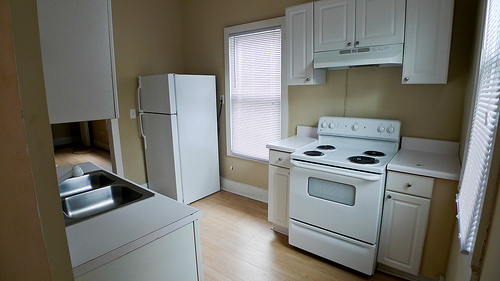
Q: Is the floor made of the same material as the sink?
A: No, the floor is made of wood and the sink is made of metal.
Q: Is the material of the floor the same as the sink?
A: No, the floor is made of wood and the sink is made of metal.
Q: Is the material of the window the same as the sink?
A: No, the window is made of glass and the sink is made of metal.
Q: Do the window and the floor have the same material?
A: No, the window is made of glass and the floor is made of wood.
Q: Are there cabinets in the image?
A: Yes, there is a cabinet.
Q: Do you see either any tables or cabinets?
A: Yes, there is a cabinet.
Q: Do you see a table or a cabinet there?
A: Yes, there is a cabinet.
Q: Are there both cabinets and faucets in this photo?
A: Yes, there are both a cabinet and a faucet.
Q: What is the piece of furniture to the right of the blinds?
A: The piece of furniture is a cabinet.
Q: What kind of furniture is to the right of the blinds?
A: The piece of furniture is a cabinet.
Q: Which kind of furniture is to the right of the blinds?
A: The piece of furniture is a cabinet.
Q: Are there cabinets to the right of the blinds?
A: Yes, there is a cabinet to the right of the blinds.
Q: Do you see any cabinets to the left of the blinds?
A: No, the cabinet is to the right of the blinds.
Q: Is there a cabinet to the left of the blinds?
A: No, the cabinet is to the right of the blinds.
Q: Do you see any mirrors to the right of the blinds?
A: No, there is a cabinet to the right of the blinds.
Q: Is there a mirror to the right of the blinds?
A: No, there is a cabinet to the right of the blinds.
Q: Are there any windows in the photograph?
A: Yes, there is a window.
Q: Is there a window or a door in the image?
A: Yes, there is a window.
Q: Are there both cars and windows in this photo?
A: No, there is a window but no cars.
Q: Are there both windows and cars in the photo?
A: No, there is a window but no cars.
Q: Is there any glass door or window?
A: Yes, there is a glass window.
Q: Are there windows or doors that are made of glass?
A: Yes, the window is made of glass.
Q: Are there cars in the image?
A: No, there are no cars.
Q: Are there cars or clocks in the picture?
A: No, there are no cars or clocks.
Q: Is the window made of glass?
A: Yes, the window is made of glass.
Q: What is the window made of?
A: The window is made of glass.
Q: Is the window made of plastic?
A: No, the window is made of glass.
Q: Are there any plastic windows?
A: No, there is a window but it is made of glass.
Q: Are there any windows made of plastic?
A: No, there is a window but it is made of glass.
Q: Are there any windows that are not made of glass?
A: No, there is a window but it is made of glass.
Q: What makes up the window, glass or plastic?
A: The window is made of glass.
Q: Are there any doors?
A: Yes, there is a door.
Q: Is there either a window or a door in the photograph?
A: Yes, there is a door.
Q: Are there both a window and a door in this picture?
A: Yes, there are both a door and a window.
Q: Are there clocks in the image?
A: No, there are no clocks.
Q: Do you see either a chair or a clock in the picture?
A: No, there are no clocks or chairs.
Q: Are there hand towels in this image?
A: No, there are no hand towels.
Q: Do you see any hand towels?
A: No, there are no hand towels.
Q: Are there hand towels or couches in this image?
A: No, there are no hand towels or couches.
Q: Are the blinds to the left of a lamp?
A: No, the blinds are to the left of the cabinet.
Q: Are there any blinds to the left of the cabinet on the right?
A: Yes, there are blinds to the left of the cabinet.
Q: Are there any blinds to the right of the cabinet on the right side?
A: No, the blinds are to the left of the cabinet.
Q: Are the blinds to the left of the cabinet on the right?
A: Yes, the blinds are to the left of the cabinet.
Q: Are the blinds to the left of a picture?
A: No, the blinds are to the left of the cabinet.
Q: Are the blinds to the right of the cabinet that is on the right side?
A: No, the blinds are to the left of the cabinet.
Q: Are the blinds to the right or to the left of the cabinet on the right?
A: The blinds are to the left of the cabinet.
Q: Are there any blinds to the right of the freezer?
A: Yes, there are blinds to the right of the freezer.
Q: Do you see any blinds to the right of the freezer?
A: Yes, there are blinds to the right of the freezer.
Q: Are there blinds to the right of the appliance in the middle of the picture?
A: Yes, there are blinds to the right of the freezer.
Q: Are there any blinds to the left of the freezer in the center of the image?
A: No, the blinds are to the right of the freezer.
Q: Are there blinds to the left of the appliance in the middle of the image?
A: No, the blinds are to the right of the freezer.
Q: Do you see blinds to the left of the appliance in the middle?
A: No, the blinds are to the right of the freezer.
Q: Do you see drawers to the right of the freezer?
A: No, there are blinds to the right of the freezer.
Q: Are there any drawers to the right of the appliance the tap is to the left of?
A: No, there are blinds to the right of the freezer.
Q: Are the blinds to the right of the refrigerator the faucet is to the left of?
A: Yes, the blinds are to the right of the freezer.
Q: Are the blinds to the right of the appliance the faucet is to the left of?
A: Yes, the blinds are to the right of the freezer.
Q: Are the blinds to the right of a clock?
A: No, the blinds are to the right of the freezer.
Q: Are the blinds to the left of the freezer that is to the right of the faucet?
A: No, the blinds are to the right of the refrigerator.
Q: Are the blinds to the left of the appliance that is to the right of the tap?
A: No, the blinds are to the right of the refrigerator.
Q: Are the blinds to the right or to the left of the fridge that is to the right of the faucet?
A: The blinds are to the right of the fridge.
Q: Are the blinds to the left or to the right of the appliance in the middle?
A: The blinds are to the right of the fridge.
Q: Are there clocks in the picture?
A: No, there are no clocks.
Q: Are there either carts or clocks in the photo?
A: No, there are no clocks or carts.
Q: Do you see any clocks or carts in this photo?
A: No, there are no clocks or carts.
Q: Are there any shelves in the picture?
A: No, there are no shelves.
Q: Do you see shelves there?
A: No, there are no shelves.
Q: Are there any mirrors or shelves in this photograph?
A: No, there are no shelves or mirrors.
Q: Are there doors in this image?
A: Yes, there is a door.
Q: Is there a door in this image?
A: Yes, there is a door.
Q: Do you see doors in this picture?
A: Yes, there is a door.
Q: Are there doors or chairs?
A: Yes, there is a door.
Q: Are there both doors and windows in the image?
A: Yes, there are both a door and a window.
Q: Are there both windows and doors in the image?
A: Yes, there are both a door and a window.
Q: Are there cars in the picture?
A: No, there are no cars.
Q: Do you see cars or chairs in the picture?
A: No, there are no cars or chairs.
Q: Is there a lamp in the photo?
A: No, there are no lamps.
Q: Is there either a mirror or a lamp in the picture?
A: No, there are no lamps or mirrors.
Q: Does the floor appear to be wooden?
A: Yes, the floor is wooden.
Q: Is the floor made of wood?
A: Yes, the floor is made of wood.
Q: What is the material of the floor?
A: The floor is made of wood.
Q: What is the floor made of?
A: The floor is made of wood.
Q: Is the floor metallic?
A: No, the floor is wooden.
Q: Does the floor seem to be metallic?
A: No, the floor is wooden.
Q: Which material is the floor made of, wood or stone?
A: The floor is made of wood.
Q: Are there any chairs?
A: No, there are no chairs.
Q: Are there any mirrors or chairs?
A: No, there are no chairs or mirrors.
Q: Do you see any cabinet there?
A: Yes, there is a cabinet.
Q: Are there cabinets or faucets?
A: Yes, there is a cabinet.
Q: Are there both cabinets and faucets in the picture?
A: Yes, there are both a cabinet and a faucet.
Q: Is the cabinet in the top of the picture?
A: Yes, the cabinet is in the top of the image.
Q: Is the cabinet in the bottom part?
A: No, the cabinet is in the top of the image.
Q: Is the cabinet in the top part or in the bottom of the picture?
A: The cabinet is in the top of the image.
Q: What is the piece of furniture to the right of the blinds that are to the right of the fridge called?
A: The piece of furniture is a cabinet.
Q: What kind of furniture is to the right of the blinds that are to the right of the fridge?
A: The piece of furniture is a cabinet.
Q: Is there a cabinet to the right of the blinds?
A: Yes, there is a cabinet to the right of the blinds.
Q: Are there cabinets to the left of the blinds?
A: No, the cabinet is to the right of the blinds.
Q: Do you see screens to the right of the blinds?
A: No, there is a cabinet to the right of the blinds.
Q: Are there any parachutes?
A: No, there are no parachutes.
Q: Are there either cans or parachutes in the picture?
A: No, there are no parachutes or cans.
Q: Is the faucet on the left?
A: Yes, the faucet is on the left of the image.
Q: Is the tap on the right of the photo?
A: No, the tap is on the left of the image.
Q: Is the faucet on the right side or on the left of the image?
A: The faucet is on the left of the image.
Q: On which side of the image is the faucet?
A: The faucet is on the left of the image.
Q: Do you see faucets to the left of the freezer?
A: Yes, there is a faucet to the left of the freezer.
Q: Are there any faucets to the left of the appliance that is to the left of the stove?
A: Yes, there is a faucet to the left of the freezer.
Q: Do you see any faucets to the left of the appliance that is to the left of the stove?
A: Yes, there is a faucet to the left of the freezer.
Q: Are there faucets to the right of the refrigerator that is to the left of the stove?
A: No, the faucet is to the left of the fridge.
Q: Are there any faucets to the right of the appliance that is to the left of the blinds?
A: No, the faucet is to the left of the fridge.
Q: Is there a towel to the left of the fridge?
A: No, there is a faucet to the left of the fridge.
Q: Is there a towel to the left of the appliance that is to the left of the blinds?
A: No, there is a faucet to the left of the fridge.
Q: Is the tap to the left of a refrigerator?
A: Yes, the tap is to the left of a refrigerator.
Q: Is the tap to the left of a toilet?
A: No, the tap is to the left of a refrigerator.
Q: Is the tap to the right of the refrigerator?
A: No, the tap is to the left of the refrigerator.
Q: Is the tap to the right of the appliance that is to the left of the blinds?
A: No, the tap is to the left of the refrigerator.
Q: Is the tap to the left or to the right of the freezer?
A: The tap is to the left of the freezer.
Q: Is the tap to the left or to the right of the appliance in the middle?
A: The tap is to the left of the freezer.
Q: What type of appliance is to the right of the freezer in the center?
A: The appliance is a stove.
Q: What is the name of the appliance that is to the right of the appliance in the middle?
A: The appliance is a stove.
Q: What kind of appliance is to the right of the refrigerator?
A: The appliance is a stove.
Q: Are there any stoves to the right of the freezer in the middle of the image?
A: Yes, there is a stove to the right of the freezer.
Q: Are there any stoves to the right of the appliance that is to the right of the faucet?
A: Yes, there is a stove to the right of the freezer.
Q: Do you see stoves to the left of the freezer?
A: No, the stove is to the right of the freezer.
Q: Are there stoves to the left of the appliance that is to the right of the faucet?
A: No, the stove is to the right of the freezer.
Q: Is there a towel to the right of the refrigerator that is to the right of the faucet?
A: No, there is a stove to the right of the freezer.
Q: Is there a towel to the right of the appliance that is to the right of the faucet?
A: No, there is a stove to the right of the freezer.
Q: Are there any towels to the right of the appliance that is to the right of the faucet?
A: No, there is a stove to the right of the freezer.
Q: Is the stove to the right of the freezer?
A: Yes, the stove is to the right of the freezer.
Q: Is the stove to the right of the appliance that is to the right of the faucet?
A: Yes, the stove is to the right of the freezer.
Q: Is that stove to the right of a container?
A: No, the stove is to the right of the freezer.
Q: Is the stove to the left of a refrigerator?
A: No, the stove is to the right of a refrigerator.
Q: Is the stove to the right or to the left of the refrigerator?
A: The stove is to the right of the refrigerator.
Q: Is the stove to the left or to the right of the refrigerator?
A: The stove is to the right of the refrigerator.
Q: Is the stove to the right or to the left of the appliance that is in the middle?
A: The stove is to the right of the refrigerator.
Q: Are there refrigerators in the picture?
A: Yes, there is a refrigerator.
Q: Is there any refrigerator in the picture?
A: Yes, there is a refrigerator.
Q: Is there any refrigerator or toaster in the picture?
A: Yes, there is a refrigerator.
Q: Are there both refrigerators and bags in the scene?
A: No, there is a refrigerator but no bags.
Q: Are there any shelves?
A: No, there are no shelves.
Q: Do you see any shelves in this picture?
A: No, there are no shelves.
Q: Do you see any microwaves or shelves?
A: No, there are no shelves or microwaves.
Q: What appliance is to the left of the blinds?
A: The appliance is a refrigerator.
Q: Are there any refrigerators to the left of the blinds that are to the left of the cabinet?
A: Yes, there is a refrigerator to the left of the blinds.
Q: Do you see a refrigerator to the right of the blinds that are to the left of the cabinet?
A: No, the refrigerator is to the left of the blinds.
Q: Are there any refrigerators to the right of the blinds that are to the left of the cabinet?
A: No, the refrigerator is to the left of the blinds.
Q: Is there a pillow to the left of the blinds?
A: No, there is a refrigerator to the left of the blinds.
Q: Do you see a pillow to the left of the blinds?
A: No, there is a refrigerator to the left of the blinds.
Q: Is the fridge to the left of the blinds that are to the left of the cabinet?
A: Yes, the fridge is to the left of the blinds.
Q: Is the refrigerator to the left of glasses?
A: No, the refrigerator is to the left of the blinds.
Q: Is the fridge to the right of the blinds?
A: No, the fridge is to the left of the blinds.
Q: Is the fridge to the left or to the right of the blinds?
A: The fridge is to the left of the blinds.